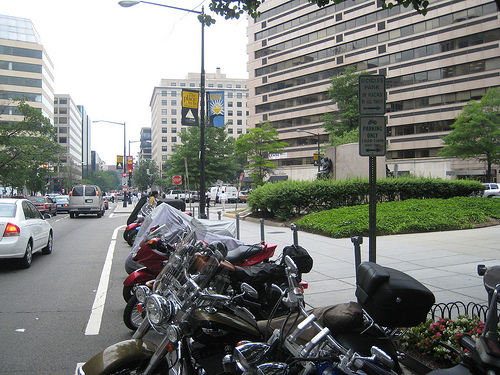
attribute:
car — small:
[3, 198, 62, 270]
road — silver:
[0, 196, 139, 371]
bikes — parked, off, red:
[92, 193, 436, 374]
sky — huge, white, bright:
[5, 0, 244, 133]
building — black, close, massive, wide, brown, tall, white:
[235, 0, 499, 184]